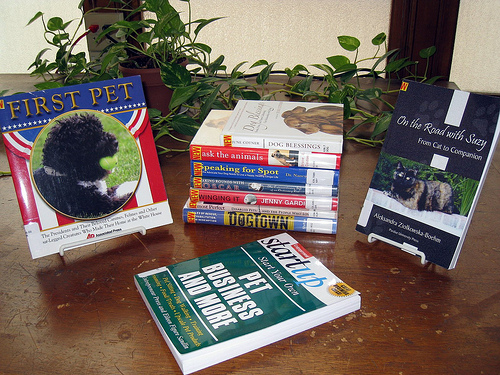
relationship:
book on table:
[178, 196, 338, 236] [1, 70, 496, 374]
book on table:
[186, 185, 341, 212] [1, 70, 496, 374]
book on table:
[221, 100, 344, 154] [1, 70, 496, 374]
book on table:
[188, 107, 342, 168] [1, 70, 496, 374]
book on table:
[188, 174, 339, 196] [1, 70, 496, 374]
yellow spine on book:
[224, 211, 296, 227] [181, 199, 337, 235]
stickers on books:
[287, 234, 361, 295] [132, 232, 362, 373]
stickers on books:
[287, 234, 361, 295] [180, 101, 342, 237]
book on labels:
[395, 85, 443, 236] [144, 237, 335, 349]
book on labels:
[134, 232, 362, 375] [144, 237, 335, 349]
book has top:
[4, 65, 176, 266] [2, 67, 148, 127]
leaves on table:
[12, 0, 444, 155] [1, 70, 496, 374]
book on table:
[196, 141, 339, 163] [2, 113, 498, 367]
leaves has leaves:
[12, 0, 444, 155] [23, 3, 430, 153]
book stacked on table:
[134, 232, 362, 375] [1, 70, 496, 374]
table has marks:
[1, 73, 500, 374] [362, 269, 452, 349]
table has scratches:
[1, 73, 500, 374] [49, 257, 158, 308]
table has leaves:
[1, 70, 496, 374] [2, 2, 442, 177]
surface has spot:
[2, 72, 499, 372] [119, 327, 132, 341]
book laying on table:
[127, 228, 364, 371] [17, 270, 142, 367]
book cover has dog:
[3, 74, 167, 252] [39, 106, 128, 210]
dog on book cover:
[39, 106, 128, 210] [3, 74, 167, 252]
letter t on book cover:
[118, 79, 138, 105] [3, 74, 167, 252]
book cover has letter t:
[3, 74, 167, 252] [118, 79, 138, 105]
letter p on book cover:
[87, 83, 103, 110] [0, 75, 173, 260]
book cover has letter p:
[0, 75, 173, 260] [87, 83, 103, 110]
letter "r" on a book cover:
[33, 93, 49, 119] [0, 75, 173, 260]